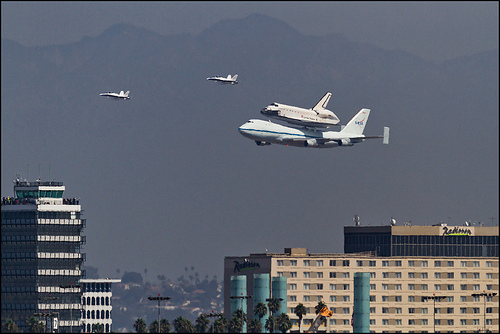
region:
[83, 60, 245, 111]
two military jets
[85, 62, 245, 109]
military jets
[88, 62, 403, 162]
military jets escorting a plane carrying a space shuttle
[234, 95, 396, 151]
airplane carrying a space shuttle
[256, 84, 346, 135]
space shuttle riding on top of an airplane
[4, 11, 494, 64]
mountains in the background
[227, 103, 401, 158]
Airplane owned by NASA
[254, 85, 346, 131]
United State space shuttle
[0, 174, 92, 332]
Tall building with an observation deck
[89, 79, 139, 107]
United States military fighter jet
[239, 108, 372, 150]
the plane is white in color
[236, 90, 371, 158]
the space shuttle is on top of a plane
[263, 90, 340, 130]
the shuttle is white in color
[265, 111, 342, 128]
the bottom of the shuttle is black in color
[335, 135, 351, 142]
the engine is under the wing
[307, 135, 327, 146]
the engine is under the wing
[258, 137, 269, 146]
the engine is under the wing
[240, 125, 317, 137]
a line runs across the plane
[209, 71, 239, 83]
a fighter plane is on the air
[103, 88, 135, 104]
a fighter plane is on the air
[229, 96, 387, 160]
space whuttle on white plane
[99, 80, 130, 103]
airplane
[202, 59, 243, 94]
airplane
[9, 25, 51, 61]
white clouds in blue sky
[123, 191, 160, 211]
white clouds in blue sky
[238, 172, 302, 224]
white clouds in blue sky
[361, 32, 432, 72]
white clouds in blue sky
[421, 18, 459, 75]
white clouds in blue sky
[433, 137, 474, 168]
white clouds in blue sky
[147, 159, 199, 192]
white clouds in blue sky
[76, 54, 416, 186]
several commercial planes in the sky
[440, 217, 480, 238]
a hotel name on the roof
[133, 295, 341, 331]
a line of green palm trees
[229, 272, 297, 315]
blue water cylinders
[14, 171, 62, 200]
an observatory on top of a building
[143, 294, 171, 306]
a row of stadium lights on pole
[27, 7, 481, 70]
a hazy blue sky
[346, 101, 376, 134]
the tail fin on plane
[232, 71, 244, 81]
the tail fin on a plane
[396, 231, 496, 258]
a row of tinted windows on a building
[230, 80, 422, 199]
plain flying with space shuttle on top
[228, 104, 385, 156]
air plane is white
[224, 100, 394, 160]
air plane has blue stripe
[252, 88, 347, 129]
space shuttle is white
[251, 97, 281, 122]
space shuttle has blue nose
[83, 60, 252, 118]
two additional planes flying in sky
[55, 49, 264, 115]
additional planes are white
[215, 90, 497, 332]
plane and space shuttle flying over building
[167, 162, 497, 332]
building below space shuttle is tan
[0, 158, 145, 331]
white and glass building in front of planes